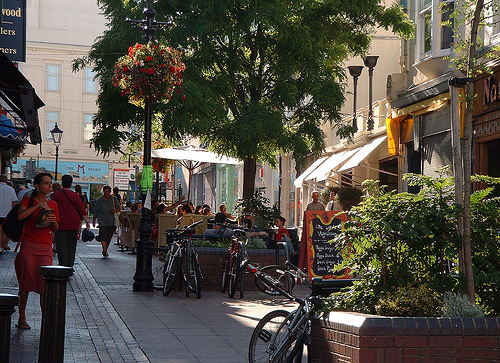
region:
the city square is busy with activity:
[6, 4, 499, 361]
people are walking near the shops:
[3, 158, 363, 323]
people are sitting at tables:
[115, 195, 295, 272]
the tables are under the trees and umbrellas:
[131, 84, 306, 270]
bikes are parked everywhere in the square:
[151, 217, 327, 357]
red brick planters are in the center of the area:
[170, 233, 494, 361]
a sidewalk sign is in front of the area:
[298, 204, 356, 290]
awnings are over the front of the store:
[288, 133, 400, 242]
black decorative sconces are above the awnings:
[342, 51, 387, 148]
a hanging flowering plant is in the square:
[81, 10, 198, 299]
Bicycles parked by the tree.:
[143, 230, 300, 312]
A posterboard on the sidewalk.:
[288, 207, 348, 275]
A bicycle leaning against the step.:
[248, 258, 330, 353]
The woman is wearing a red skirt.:
[20, 236, 62, 291]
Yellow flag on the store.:
[373, 105, 418, 155]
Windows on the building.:
[41, 61, 103, 126]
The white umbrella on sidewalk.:
[153, 130, 272, 172]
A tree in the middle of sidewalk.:
[178, 12, 316, 198]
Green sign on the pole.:
[138, 158, 162, 190]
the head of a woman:
[24, 165, 63, 210]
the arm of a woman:
[13, 185, 73, 227]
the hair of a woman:
[18, 144, 108, 207]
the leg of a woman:
[10, 245, 32, 327]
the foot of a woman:
[14, 304, 41, 333]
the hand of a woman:
[24, 197, 71, 222]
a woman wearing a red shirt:
[16, 146, 104, 261]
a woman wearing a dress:
[13, 221, 111, 305]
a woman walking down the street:
[8, 118, 131, 323]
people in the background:
[44, 139, 219, 261]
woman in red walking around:
[7, 170, 59, 327]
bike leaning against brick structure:
[249, 285, 328, 360]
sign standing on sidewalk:
[307, 210, 353, 278]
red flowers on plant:
[147, 51, 174, 83]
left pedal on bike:
[258, 327, 273, 345]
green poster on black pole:
[138, 162, 155, 190]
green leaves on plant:
[342, 181, 421, 288]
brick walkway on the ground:
[67, 316, 121, 360]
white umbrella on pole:
[148, 143, 244, 170]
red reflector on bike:
[245, 267, 261, 277]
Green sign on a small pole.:
[138, 163, 155, 190]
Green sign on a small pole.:
[343, 58, 363, 88]